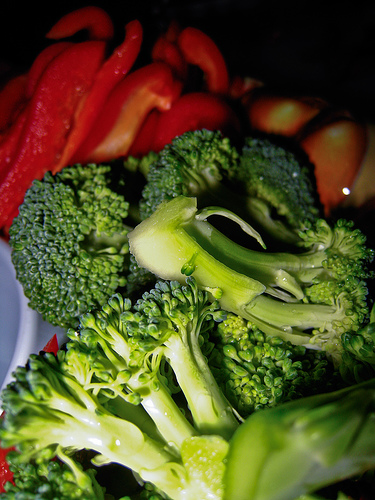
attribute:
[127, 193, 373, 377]
broccoli — green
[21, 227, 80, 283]
bulbs — little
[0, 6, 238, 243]
pepper — sweet, red, cut, sliced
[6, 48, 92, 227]
pepper — red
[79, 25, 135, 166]
pepper — red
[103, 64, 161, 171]
pepper — red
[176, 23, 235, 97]
pepper — red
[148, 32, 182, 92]
pepper — red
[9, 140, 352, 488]
broccoli — green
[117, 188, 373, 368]
broccoli — green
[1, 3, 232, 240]
peppers — sliced, red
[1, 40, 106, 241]
pepper — red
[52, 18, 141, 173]
pepper — red, long slices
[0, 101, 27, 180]
pepper — red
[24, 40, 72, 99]
pepper — red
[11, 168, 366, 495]
broccoli — green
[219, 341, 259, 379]
floret — broccoli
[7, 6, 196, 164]
pepper — sliced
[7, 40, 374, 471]
vegetables — close up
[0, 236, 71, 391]
plate — white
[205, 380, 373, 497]
broccoli stem — blurred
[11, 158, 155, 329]
piece — top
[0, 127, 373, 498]
broccoli — cut, raw, green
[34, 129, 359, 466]
vegetables — cut, raw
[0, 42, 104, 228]
pepper — long slices, red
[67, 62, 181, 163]
pepper — long slices, red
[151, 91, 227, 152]
pepper — long slices, red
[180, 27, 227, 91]
pepper — long slices, red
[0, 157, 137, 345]
broccoli — green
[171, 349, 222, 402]
stem — broccoli, light green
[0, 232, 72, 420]
plate — white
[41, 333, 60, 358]
red pepper — tip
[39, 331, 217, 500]
light — shining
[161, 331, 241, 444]
stem — green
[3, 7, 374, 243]
pepper — sliced, bright red